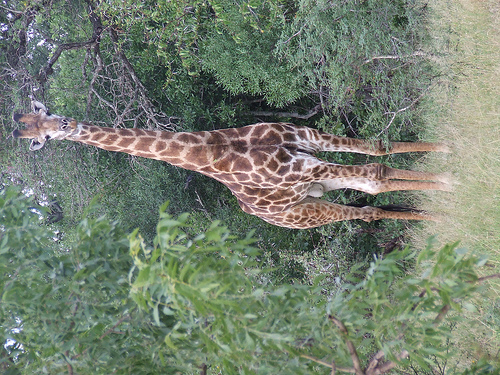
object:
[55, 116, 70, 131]
nose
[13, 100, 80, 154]
head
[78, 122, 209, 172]
long neck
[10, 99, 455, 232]
giraffe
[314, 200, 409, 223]
leg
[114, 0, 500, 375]
plants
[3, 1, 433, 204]
tree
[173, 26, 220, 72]
leaf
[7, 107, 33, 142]
ossicones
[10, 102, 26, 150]
laptop keyboard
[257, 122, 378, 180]
spotted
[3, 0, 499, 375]
forest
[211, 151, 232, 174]
spot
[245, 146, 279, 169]
spot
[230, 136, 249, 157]
spot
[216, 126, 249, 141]
spot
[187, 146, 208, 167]
spot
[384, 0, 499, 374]
grass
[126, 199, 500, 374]
bush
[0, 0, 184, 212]
branches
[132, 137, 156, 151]
spot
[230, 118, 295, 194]
chest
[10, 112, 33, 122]
horn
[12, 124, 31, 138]
horn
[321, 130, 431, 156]
leg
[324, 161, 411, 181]
leg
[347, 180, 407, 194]
leg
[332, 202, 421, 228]
leg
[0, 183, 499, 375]
trees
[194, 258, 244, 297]
leaf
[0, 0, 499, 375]
field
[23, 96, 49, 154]
ears